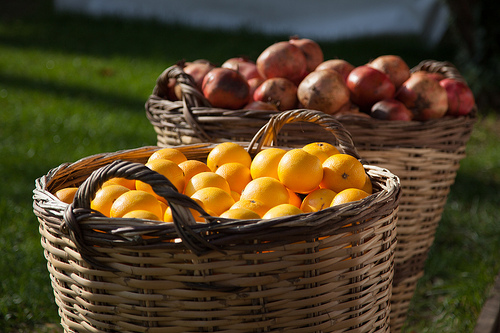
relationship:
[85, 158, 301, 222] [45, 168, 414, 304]
food in basket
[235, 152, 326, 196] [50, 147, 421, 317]
fruit in basket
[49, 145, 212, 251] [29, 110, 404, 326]
handle of basket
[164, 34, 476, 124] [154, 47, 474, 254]
food in basket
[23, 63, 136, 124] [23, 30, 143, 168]
shadow on ground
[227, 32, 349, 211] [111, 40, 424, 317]
food inside baskets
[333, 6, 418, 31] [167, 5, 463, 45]
wall on side building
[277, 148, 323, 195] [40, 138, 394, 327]
lemon in basket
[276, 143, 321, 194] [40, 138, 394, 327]
lemon in basket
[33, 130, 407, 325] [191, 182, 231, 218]
lemon in basket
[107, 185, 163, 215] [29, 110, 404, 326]
lemon in basket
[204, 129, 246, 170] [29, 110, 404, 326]
lemon in basket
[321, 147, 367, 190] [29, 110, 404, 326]
lemon in basket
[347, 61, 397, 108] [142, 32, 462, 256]
potato in basket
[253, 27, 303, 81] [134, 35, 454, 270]
potato in basket